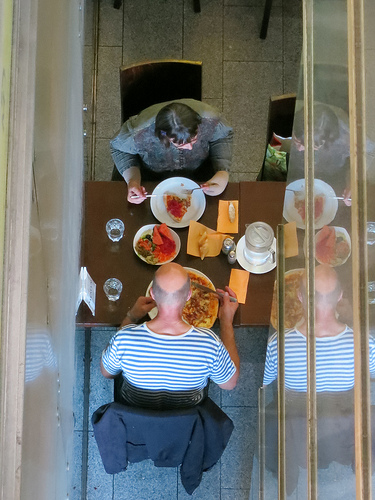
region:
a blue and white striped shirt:
[101, 319, 236, 405]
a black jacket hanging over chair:
[91, 401, 234, 495]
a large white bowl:
[132, 222, 180, 264]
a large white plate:
[150, 176, 206, 228]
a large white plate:
[145, 266, 217, 332]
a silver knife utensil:
[191, 281, 236, 303]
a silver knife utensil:
[127, 192, 173, 197]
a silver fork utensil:
[178, 184, 211, 194]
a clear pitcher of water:
[243, 220, 276, 268]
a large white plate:
[236, 232, 275, 273]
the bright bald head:
[149, 263, 189, 303]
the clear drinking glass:
[102, 277, 122, 301]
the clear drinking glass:
[105, 218, 125, 242]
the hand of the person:
[132, 294, 157, 318]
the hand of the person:
[216, 287, 238, 320]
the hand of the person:
[125, 182, 147, 206]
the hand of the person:
[202, 173, 228, 196]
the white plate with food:
[133, 223, 180, 262]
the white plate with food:
[150, 175, 205, 227]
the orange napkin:
[185, 220, 231, 259]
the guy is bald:
[163, 266, 179, 285]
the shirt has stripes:
[157, 343, 176, 362]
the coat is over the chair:
[136, 408, 163, 428]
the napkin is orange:
[234, 276, 241, 289]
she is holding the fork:
[197, 178, 210, 195]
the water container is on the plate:
[248, 240, 265, 270]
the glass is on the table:
[113, 228, 125, 245]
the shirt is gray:
[142, 140, 158, 156]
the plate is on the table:
[142, 208, 160, 219]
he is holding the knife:
[215, 286, 238, 306]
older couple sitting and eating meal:
[75, 57, 296, 495]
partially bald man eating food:
[90, 260, 241, 494]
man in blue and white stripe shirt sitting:
[88, 262, 244, 496]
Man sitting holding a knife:
[90, 259, 248, 492]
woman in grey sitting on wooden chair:
[107, 57, 238, 204]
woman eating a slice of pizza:
[108, 92, 234, 228]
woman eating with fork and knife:
[110, 93, 238, 229]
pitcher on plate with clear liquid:
[233, 218, 276, 276]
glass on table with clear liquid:
[98, 215, 126, 245]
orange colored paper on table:
[226, 265, 250, 308]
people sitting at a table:
[125, 109, 209, 313]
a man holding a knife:
[193, 280, 250, 316]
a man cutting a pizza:
[194, 281, 237, 308]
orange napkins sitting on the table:
[195, 213, 278, 297]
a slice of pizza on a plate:
[155, 191, 191, 231]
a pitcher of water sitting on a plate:
[243, 223, 273, 279]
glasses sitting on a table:
[92, 210, 134, 301]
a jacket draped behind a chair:
[82, 403, 245, 471]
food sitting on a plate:
[129, 222, 178, 263]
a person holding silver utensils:
[120, 182, 270, 207]